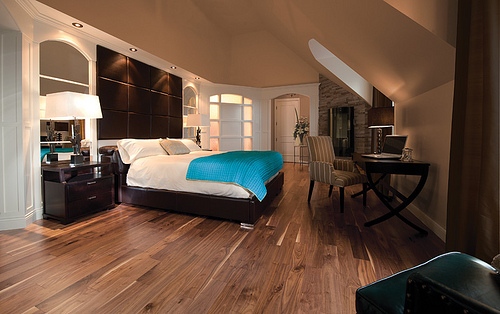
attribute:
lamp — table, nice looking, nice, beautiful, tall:
[43, 90, 105, 163]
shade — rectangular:
[42, 92, 103, 122]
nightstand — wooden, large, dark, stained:
[41, 157, 120, 228]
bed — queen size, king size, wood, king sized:
[98, 132, 289, 222]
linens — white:
[117, 131, 285, 198]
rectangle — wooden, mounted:
[94, 47, 133, 86]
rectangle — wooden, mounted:
[99, 110, 130, 142]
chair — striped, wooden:
[293, 128, 365, 208]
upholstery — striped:
[303, 133, 361, 192]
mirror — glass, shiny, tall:
[41, 35, 93, 170]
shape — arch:
[36, 44, 97, 155]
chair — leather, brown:
[352, 239, 500, 311]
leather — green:
[361, 252, 499, 308]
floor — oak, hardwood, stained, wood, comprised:
[8, 150, 440, 308]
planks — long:
[4, 144, 440, 306]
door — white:
[275, 99, 301, 161]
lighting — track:
[61, 16, 208, 82]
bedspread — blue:
[187, 143, 286, 197]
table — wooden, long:
[352, 144, 437, 235]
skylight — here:
[307, 33, 378, 115]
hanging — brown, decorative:
[94, 44, 184, 146]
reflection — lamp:
[39, 97, 74, 156]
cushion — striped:
[317, 157, 351, 179]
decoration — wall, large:
[93, 39, 189, 143]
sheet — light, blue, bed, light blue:
[189, 140, 286, 203]